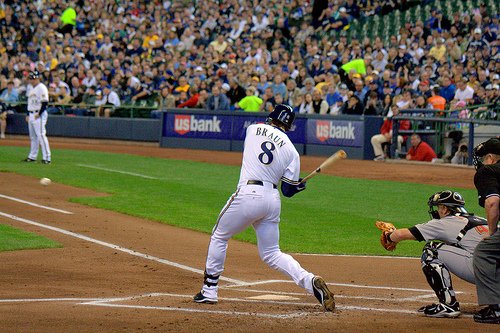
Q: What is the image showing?
A: It is showing a field.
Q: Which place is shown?
A: It is a field.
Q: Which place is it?
A: It is a field.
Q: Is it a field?
A: Yes, it is a field.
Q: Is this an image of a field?
A: Yes, it is showing a field.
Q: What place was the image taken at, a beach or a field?
A: It was taken at a field.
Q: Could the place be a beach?
A: No, it is a field.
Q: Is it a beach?
A: No, it is a field.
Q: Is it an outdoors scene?
A: Yes, it is outdoors.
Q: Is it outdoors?
A: Yes, it is outdoors.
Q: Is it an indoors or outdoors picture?
A: It is outdoors.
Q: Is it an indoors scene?
A: No, it is outdoors.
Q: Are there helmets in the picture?
A: Yes, there is a helmet.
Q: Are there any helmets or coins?
A: Yes, there is a helmet.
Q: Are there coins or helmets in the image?
A: Yes, there is a helmet.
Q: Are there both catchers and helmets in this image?
A: Yes, there are both a helmet and a catcher.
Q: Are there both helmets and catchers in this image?
A: Yes, there are both a helmet and a catcher.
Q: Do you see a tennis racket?
A: No, there are no rackets.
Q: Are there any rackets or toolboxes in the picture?
A: No, there are no rackets or toolboxes.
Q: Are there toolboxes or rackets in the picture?
A: No, there are no rackets or toolboxes.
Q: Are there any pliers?
A: No, there are no pliers.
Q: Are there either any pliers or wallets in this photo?
A: No, there are no pliers or wallets.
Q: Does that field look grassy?
A: Yes, the field is grassy.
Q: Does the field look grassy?
A: Yes, the field is grassy.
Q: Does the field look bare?
A: No, the field is grassy.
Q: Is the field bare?
A: No, the field is grassy.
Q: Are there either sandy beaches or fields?
A: No, there is a field but it is grassy.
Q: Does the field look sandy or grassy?
A: The field is grassy.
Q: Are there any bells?
A: No, there are no bells.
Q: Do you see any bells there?
A: No, there are no bells.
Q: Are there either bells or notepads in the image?
A: No, there are no bells or notepads.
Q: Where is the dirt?
A: The dirt is on the field.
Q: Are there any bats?
A: Yes, there is a bat.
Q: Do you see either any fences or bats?
A: Yes, there is a bat.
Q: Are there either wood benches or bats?
A: Yes, there is a wood bat.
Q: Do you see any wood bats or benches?
A: Yes, there is a wood bat.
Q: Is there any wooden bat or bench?
A: Yes, there is a wood bat.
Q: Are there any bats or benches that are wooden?
A: Yes, the bat is wooden.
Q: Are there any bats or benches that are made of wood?
A: Yes, the bat is made of wood.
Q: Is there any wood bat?
A: Yes, there is a bat that is made of wood.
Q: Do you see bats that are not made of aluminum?
A: Yes, there is a bat that is made of wood.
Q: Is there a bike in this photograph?
A: No, there are no bikes.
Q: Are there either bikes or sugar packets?
A: No, there are no bikes or sugar packets.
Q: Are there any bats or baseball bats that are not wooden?
A: No, there is a bat but it is wooden.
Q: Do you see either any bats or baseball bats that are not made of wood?
A: No, there is a bat but it is made of wood.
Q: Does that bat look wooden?
A: Yes, the bat is wooden.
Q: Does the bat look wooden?
A: Yes, the bat is wooden.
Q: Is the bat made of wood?
A: Yes, the bat is made of wood.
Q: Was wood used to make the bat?
A: Yes, the bat is made of wood.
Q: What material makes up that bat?
A: The bat is made of wood.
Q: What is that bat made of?
A: The bat is made of wood.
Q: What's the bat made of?
A: The bat is made of wood.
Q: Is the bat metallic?
A: No, the bat is wooden.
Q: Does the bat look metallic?
A: No, the bat is wooden.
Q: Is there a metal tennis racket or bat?
A: No, there is a bat but it is wooden.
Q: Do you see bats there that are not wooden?
A: No, there is a bat but it is wooden.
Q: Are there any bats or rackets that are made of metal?
A: No, there is a bat but it is made of wood.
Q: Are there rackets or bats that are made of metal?
A: No, there is a bat but it is made of wood.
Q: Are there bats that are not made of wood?
A: No, there is a bat but it is made of wood.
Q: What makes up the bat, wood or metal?
A: The bat is made of wood.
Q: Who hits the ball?
A: The player hits the ball.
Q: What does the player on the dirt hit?
A: The player hits the ball.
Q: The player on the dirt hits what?
A: The player hits the ball.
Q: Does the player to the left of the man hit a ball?
A: Yes, the player hits a ball.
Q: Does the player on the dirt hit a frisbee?
A: No, the player hits a ball.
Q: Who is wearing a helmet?
A: The player is wearing a helmet.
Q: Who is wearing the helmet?
A: The player is wearing a helmet.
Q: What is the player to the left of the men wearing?
A: The player is wearing a helmet.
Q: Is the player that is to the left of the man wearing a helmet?
A: Yes, the player is wearing a helmet.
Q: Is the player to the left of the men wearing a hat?
A: No, the player is wearing a helmet.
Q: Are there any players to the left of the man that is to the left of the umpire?
A: Yes, there is a player to the left of the man.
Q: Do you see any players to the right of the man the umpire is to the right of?
A: No, the player is to the left of the man.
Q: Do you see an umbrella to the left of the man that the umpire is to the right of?
A: No, there is a player to the left of the man.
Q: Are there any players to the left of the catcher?
A: Yes, there is a player to the left of the catcher.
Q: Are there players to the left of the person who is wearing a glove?
A: Yes, there is a player to the left of the catcher.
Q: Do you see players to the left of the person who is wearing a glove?
A: Yes, there is a player to the left of the catcher.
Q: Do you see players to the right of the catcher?
A: No, the player is to the left of the catcher.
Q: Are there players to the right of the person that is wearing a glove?
A: No, the player is to the left of the catcher.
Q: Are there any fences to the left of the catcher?
A: No, there is a player to the left of the catcher.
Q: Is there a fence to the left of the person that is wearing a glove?
A: No, there is a player to the left of the catcher.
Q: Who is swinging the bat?
A: The player is swinging the bat.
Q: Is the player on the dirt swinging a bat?
A: Yes, the player is swinging a bat.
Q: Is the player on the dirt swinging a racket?
A: No, the player is swinging a bat.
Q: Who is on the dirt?
A: The player is on the dirt.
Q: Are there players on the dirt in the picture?
A: Yes, there is a player on the dirt.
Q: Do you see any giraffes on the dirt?
A: No, there is a player on the dirt.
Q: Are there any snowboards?
A: No, there are no snowboards.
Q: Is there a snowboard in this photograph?
A: No, there are no snowboards.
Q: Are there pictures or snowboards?
A: No, there are no snowboards or pictures.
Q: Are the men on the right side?
A: Yes, the men are on the right of the image.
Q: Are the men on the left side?
A: No, the men are on the right of the image.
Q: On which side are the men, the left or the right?
A: The men are on the right of the image.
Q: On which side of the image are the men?
A: The men are on the right of the image.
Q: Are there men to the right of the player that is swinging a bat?
A: Yes, there are men to the right of the player.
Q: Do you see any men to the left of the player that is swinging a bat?
A: No, the men are to the right of the player.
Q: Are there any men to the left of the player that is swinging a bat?
A: No, the men are to the right of the player.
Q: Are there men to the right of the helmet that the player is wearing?
A: Yes, there are men to the right of the helmet.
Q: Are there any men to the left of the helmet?
A: No, the men are to the right of the helmet.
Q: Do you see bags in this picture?
A: No, there are no bags.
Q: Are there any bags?
A: No, there are no bags.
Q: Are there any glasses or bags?
A: No, there are no bags or glasses.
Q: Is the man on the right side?
A: Yes, the man is on the right of the image.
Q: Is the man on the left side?
A: No, the man is on the right of the image.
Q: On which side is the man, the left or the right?
A: The man is on the right of the image.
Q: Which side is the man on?
A: The man is on the right of the image.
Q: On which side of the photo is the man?
A: The man is on the right of the image.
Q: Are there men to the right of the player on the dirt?
A: Yes, there is a man to the right of the player.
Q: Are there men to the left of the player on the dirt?
A: No, the man is to the right of the player.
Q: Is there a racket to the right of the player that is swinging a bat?
A: No, there is a man to the right of the player.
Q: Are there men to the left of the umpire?
A: Yes, there is a man to the left of the umpire.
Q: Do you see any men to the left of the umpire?
A: Yes, there is a man to the left of the umpire.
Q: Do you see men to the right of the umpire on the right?
A: No, the man is to the left of the umpire.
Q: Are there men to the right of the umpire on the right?
A: No, the man is to the left of the umpire.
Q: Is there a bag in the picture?
A: No, there are no bags.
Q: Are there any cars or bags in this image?
A: No, there are no bags or cars.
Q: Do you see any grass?
A: Yes, there is grass.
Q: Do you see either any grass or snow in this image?
A: Yes, there is grass.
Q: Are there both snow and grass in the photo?
A: No, there is grass but no snow.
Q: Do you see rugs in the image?
A: No, there are no rugs.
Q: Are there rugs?
A: No, there are no rugs.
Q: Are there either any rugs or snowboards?
A: No, there are no rugs or snowboards.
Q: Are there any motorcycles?
A: No, there are no motorcycles.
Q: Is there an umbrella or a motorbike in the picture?
A: No, there are no motorcycles or umbrellas.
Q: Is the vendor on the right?
A: Yes, the vendor is on the right of the image.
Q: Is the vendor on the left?
A: No, the vendor is on the right of the image.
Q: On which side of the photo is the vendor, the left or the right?
A: The vendor is on the right of the image.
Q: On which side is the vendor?
A: The vendor is on the right of the image.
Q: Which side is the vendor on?
A: The vendor is on the right of the image.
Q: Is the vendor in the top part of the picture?
A: Yes, the vendor is in the top of the image.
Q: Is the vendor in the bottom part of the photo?
A: No, the vendor is in the top of the image.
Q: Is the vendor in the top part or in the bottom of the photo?
A: The vendor is in the top of the image.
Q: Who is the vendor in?
A: The vendor is in the crowd.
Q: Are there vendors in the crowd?
A: Yes, there is a vendor in the crowd.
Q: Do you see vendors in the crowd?
A: Yes, there is a vendor in the crowd.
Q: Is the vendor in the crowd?
A: Yes, the vendor is in the crowd.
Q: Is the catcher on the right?
A: Yes, the catcher is on the right of the image.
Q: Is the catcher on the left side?
A: No, the catcher is on the right of the image.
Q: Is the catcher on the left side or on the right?
A: The catcher is on the right of the image.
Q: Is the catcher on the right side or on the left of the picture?
A: The catcher is on the right of the image.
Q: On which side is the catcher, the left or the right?
A: The catcher is on the right of the image.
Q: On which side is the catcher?
A: The catcher is on the right of the image.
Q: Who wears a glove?
A: The catcher wears a glove.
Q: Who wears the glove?
A: The catcher wears a glove.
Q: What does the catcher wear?
A: The catcher wears a glove.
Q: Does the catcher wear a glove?
A: Yes, the catcher wears a glove.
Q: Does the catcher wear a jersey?
A: No, the catcher wears a glove.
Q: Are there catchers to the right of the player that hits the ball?
A: Yes, there is a catcher to the right of the player.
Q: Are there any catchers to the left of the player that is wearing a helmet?
A: No, the catcher is to the right of the player.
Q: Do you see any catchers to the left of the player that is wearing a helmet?
A: No, the catcher is to the right of the player.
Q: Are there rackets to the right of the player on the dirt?
A: No, there is a catcher to the right of the player.